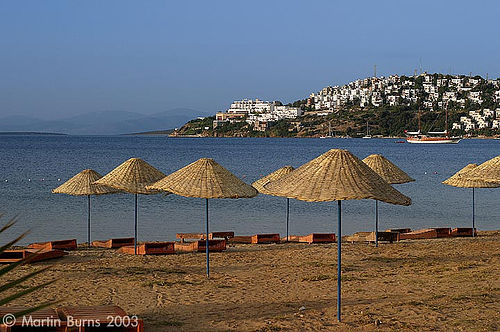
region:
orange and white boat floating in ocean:
[398, 108, 462, 145]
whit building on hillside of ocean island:
[173, 71, 304, 137]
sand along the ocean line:
[353, 255, 496, 330]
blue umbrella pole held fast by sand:
[333, 208, 348, 323]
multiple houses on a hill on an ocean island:
[296, 66, 498, 131]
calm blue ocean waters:
[8, 132, 110, 167]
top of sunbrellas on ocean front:
[51, 150, 410, 208]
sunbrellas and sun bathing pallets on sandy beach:
[40, 148, 281, 277]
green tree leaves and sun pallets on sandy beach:
[0, 231, 98, 308]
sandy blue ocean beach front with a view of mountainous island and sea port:
[8, 71, 499, 312]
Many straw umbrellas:
[42, 138, 499, 328]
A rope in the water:
[8, 169, 97, 187]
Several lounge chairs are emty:
[34, 217, 476, 263]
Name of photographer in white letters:
[1, 308, 151, 330]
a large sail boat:
[396, 109, 466, 159]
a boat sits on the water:
[401, 106, 470, 162]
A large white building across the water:
[208, 92, 317, 145]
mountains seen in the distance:
[13, 98, 208, 135]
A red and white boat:
[406, 106, 468, 149]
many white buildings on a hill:
[308, 53, 491, 139]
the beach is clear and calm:
[80, 91, 387, 329]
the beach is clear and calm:
[126, 159, 176, 222]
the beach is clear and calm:
[104, 39, 293, 291]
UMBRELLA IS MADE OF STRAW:
[275, 147, 405, 212]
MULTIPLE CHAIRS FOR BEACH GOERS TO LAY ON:
[11, 225, 485, 249]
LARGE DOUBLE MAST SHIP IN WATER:
[393, 105, 467, 149]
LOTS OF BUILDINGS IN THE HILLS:
[139, 66, 496, 138]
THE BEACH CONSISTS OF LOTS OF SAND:
[98, 259, 498, 330]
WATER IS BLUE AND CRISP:
[17, 132, 322, 157]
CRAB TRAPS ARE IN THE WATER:
[1, 172, 78, 188]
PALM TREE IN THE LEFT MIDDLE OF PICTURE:
[0, 217, 70, 299]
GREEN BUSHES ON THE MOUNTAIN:
[331, 105, 453, 130]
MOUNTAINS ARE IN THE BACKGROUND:
[2, 110, 200, 140]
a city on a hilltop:
[220, 87, 487, 136]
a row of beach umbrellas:
[67, 157, 493, 274]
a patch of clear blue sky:
[12, 8, 484, 85]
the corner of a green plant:
[6, 228, 71, 302]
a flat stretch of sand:
[36, 262, 476, 323]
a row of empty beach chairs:
[23, 234, 458, 259]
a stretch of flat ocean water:
[30, 147, 495, 217]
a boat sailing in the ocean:
[395, 120, 465, 159]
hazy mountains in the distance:
[10, 111, 176, 136]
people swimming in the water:
[416, 162, 441, 180]